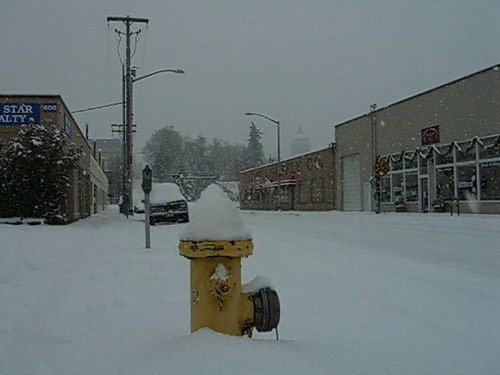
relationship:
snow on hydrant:
[187, 187, 252, 255] [156, 223, 300, 356]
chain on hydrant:
[252, 336, 286, 348] [156, 223, 300, 356]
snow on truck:
[187, 187, 252, 255] [137, 177, 189, 225]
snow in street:
[187, 187, 252, 255] [245, 220, 450, 347]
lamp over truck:
[157, 62, 190, 80] [137, 177, 189, 225]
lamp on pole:
[157, 62, 190, 80] [129, 52, 147, 223]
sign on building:
[1, 87, 54, 129] [9, 103, 114, 228]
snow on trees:
[187, 187, 252, 255] [145, 98, 272, 202]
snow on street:
[187, 187, 252, 255] [245, 220, 450, 347]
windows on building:
[389, 154, 498, 210] [343, 75, 496, 239]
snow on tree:
[187, 187, 252, 255] [2, 128, 60, 224]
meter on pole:
[135, 162, 179, 237] [143, 193, 158, 250]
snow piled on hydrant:
[187, 187, 252, 255] [156, 223, 300, 356]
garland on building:
[382, 130, 497, 163] [343, 75, 496, 239]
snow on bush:
[187, 187, 252, 255] [4, 127, 97, 239]